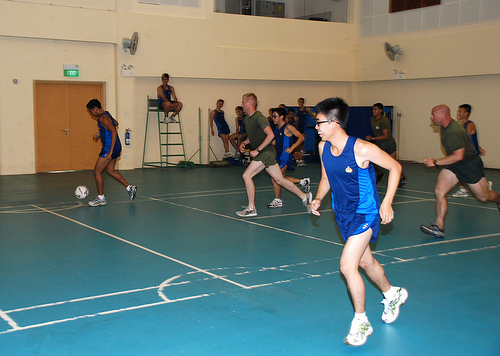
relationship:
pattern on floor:
[0, 157, 484, 353] [0, 157, 484, 353]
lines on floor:
[4, 183, 483, 333] [0, 157, 484, 353]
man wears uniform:
[305, 94, 404, 347] [321, 144, 383, 242]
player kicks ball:
[86, 99, 137, 206] [71, 180, 93, 202]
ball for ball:
[71, 180, 93, 202] [74, 184, 91, 200]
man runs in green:
[422, 102, 499, 236] [446, 126, 468, 151]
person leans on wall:
[213, 98, 235, 160] [1, 10, 358, 163]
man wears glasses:
[305, 94, 404, 347] [310, 110, 341, 131]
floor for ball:
[0, 157, 484, 353] [74, 184, 91, 200]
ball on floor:
[71, 180, 93, 202] [0, 157, 484, 353]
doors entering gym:
[35, 66, 111, 174] [1, 5, 498, 354]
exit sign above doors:
[58, 63, 90, 82] [35, 66, 111, 174]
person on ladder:
[158, 73, 185, 121] [158, 105, 183, 167]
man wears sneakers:
[305, 94, 404, 347] [343, 285, 416, 348]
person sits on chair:
[158, 73, 185, 121] [139, 94, 190, 171]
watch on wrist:
[430, 155, 443, 174] [253, 142, 267, 159]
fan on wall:
[113, 27, 147, 65] [1, 10, 358, 163]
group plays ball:
[82, 73, 500, 347] [74, 184, 91, 200]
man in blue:
[305, 94, 404, 347] [273, 121, 298, 167]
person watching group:
[158, 73, 185, 121] [82, 73, 500, 347]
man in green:
[422, 102, 499, 236] [446, 126, 468, 151]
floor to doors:
[0, 157, 484, 353] [35, 66, 111, 174]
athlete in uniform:
[86, 99, 137, 206] [321, 144, 383, 242]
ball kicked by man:
[71, 180, 93, 202] [86, 99, 137, 206]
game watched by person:
[82, 73, 500, 347] [158, 73, 185, 121]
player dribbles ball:
[86, 99, 137, 206] [71, 180, 93, 202]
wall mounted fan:
[1, 10, 358, 163] [113, 27, 147, 65]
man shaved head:
[422, 102, 499, 236] [420, 102, 460, 133]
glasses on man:
[310, 110, 341, 131] [305, 94, 404, 347]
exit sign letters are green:
[58, 63, 90, 82] [69, 69, 80, 79]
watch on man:
[430, 155, 443, 174] [422, 102, 499, 236]